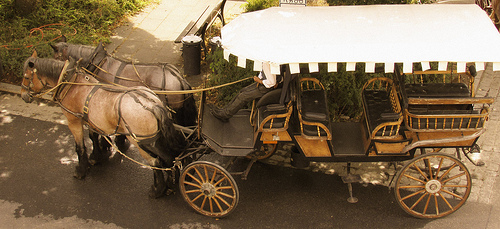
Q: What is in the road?
A: Vehicle.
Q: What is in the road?
A: Wheel.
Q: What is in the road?
A: Thread.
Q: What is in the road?
A: Bulcort.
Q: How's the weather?
A: Sunny.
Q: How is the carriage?
A: Covered.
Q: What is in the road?
A: Wheel.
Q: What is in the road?
A: Seats.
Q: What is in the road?
A: Horse.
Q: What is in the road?
A: Roof.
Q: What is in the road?
A: Carriage.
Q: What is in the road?
A: Horse.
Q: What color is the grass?
A: Green.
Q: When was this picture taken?
A: During the day.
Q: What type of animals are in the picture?
A: Horses.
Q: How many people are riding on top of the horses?
A: Zero.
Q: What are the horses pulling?
A: A cart.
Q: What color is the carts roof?
A: White.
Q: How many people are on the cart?
A: One.